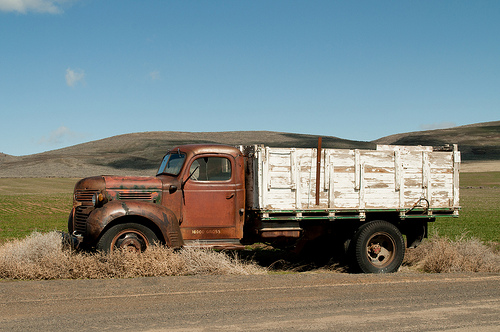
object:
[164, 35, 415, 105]
sky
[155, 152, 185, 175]
window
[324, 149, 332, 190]
board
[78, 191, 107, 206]
headlight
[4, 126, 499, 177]
hill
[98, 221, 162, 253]
wheel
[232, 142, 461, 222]
truck bed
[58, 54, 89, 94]
cloud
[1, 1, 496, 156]
sky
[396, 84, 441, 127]
ground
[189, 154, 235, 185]
window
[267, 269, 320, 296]
road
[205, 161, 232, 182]
window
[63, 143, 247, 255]
cab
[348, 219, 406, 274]
wheel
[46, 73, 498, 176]
hill tops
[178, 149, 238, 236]
door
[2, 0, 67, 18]
cloud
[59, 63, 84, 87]
cloud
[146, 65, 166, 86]
cloud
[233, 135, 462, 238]
truck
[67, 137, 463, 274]
truck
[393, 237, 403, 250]
part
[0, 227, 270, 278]
bush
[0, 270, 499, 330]
road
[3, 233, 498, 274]
grass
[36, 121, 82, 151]
cloud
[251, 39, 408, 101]
sky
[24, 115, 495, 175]
hills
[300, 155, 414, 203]
wood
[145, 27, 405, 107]
sky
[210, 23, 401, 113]
sky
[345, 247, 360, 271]
edge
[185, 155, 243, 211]
part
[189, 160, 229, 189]
part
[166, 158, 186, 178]
part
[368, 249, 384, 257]
part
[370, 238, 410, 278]
part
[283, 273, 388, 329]
part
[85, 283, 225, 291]
edge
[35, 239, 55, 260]
part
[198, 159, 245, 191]
part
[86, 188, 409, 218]
side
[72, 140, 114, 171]
edge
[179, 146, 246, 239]
door